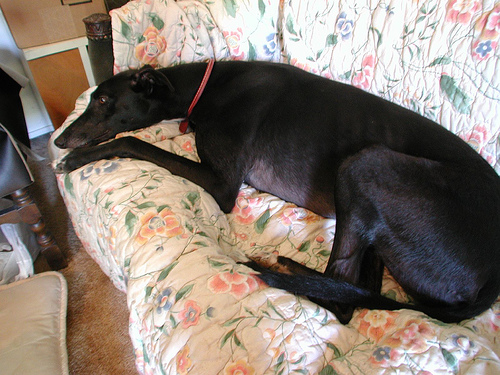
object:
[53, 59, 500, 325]
dog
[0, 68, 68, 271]
table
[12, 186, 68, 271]
leg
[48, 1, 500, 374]
couch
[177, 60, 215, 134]
collar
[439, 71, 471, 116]
print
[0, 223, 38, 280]
bag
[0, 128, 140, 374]
floor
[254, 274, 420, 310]
tail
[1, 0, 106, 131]
wall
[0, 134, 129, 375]
carpet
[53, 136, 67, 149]
snout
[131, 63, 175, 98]
ear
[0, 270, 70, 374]
cushion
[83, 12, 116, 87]
canister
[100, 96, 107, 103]
eye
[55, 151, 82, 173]
paw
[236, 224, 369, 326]
leg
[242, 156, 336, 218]
stomach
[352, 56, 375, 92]
flower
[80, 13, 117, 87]
post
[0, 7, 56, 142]
door